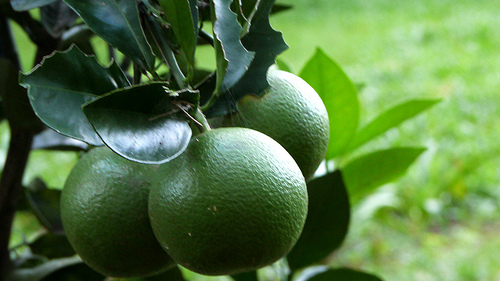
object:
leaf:
[19, 42, 114, 148]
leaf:
[78, 79, 194, 167]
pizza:
[294, 38, 359, 156]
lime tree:
[0, 0, 445, 281]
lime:
[141, 121, 312, 278]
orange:
[57, 143, 181, 275]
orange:
[223, 49, 332, 174]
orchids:
[76, 6, 297, 158]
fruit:
[60, 146, 177, 276]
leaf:
[282, 165, 352, 272]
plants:
[371, 0, 499, 246]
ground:
[269, 0, 499, 280]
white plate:
[146, 63, 344, 273]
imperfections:
[160, 194, 246, 255]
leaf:
[341, 146, 426, 206]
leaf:
[341, 96, 449, 158]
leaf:
[66, 0, 155, 85]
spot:
[204, 182, 223, 222]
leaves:
[21, 174, 69, 238]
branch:
[160, 40, 217, 130]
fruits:
[195, 66, 335, 185]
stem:
[140, 19, 210, 129]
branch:
[7, 8, 129, 88]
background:
[251, 0, 500, 179]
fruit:
[145, 122, 312, 278]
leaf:
[288, 41, 365, 170]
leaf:
[201, 0, 259, 112]